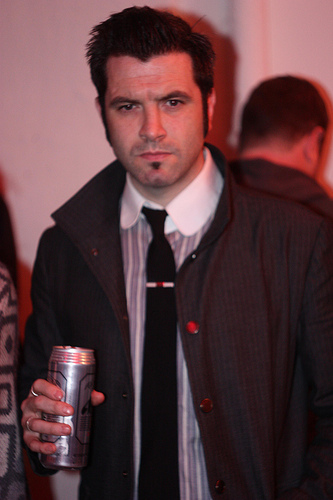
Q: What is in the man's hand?
A: Can.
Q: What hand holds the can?
A: Right.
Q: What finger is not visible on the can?
A: Pinky.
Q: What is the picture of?
A: A man.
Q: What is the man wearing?
A: A shirt.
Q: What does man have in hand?
A: A can.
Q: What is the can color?
A: Silver.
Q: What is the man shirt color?
A: Grey and white.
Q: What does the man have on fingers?
A: Rings.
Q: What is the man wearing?
A: A jacket.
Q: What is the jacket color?
A: Black.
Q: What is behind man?
A: Another man.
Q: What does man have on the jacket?
A: Buttons.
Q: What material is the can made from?
A: Aluminum.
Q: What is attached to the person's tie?
A: Tie tack.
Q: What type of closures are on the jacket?
A: Snaps.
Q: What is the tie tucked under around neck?
A: Collar.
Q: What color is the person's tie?
A: Black.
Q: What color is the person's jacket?
A: Grey.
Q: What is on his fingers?
A: Rings.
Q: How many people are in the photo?
A: 3.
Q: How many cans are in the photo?
A: 1.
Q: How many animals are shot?
A: 0.